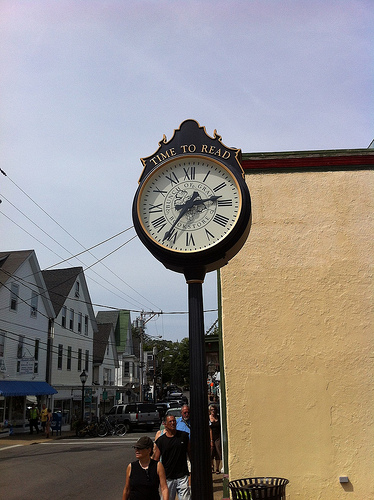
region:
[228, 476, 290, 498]
A black trash bin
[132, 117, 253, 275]
An analog clock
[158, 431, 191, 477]
A person wearing a black shirt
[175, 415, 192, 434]
A person wearing a blue shirt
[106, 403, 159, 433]
A parked SUV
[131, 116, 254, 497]
clock says time to read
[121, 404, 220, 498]
people are walking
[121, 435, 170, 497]
man has on a black shirt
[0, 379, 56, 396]
building has a blue awning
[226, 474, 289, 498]
trash can is black and full of trash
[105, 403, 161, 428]
car is large and white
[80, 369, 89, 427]
lamp post is black and white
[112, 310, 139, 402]
house has a green roof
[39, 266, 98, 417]
white house has a gray roof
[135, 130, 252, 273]
black and white clock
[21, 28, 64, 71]
white clouds in blue sky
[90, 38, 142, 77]
white clouds in blue sky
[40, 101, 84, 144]
white clouds in blue sky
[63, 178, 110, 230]
white clouds in blue sky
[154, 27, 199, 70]
white clouds in blue sky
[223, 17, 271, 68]
white clouds in blue sky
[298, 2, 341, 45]
white clouds in blue sky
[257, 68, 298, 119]
white clouds in blue sky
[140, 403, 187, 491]
People walking on the sidewalk.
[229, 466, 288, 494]
Garbage can near the wall.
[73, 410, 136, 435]
Bikes parked on the side of road.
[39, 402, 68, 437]
Person standing next to the mailbox.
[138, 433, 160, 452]
The person is wearing a black cap.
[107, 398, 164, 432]
A SUV parked on the street.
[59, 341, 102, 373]
Windows on the building.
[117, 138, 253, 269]
A clock on the pole.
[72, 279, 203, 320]
Wires hanging across the buildings.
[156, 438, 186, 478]
The shirt is black.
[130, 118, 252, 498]
A large clock near the street.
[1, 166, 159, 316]
Power lines in the air.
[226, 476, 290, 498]
The top of the trashcan.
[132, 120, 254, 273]
wording on clock says "TIME TO READ"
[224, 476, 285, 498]
basket for garbage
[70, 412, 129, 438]
bikes are all parked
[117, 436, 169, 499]
woman wearing a hat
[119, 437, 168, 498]
woman wearing a sleevless black shirt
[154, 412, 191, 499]
man wearing a sleevless black shirt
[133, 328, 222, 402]
green trees in the background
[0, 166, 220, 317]
powerlines hanging over the street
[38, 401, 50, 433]
person wearing a yellow shirt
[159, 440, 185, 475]
black shirt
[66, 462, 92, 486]
the street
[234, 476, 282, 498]
a trashcan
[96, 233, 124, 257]
an electrical line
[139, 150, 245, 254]
a clock